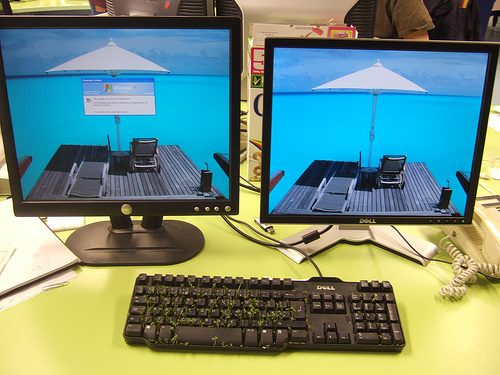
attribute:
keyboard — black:
[122, 272, 405, 353]